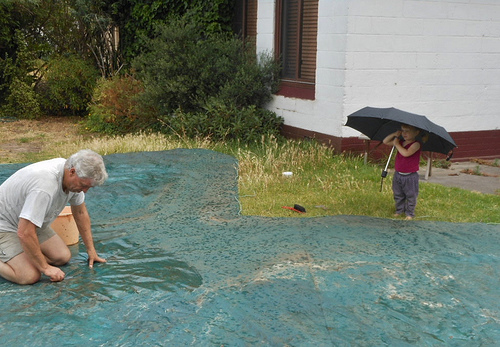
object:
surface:
[0, 236, 202, 345]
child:
[382, 123, 421, 221]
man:
[0, 150, 107, 284]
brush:
[84, 4, 287, 147]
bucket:
[48, 205, 81, 247]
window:
[227, 1, 257, 64]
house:
[220, 2, 497, 158]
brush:
[282, 204, 306, 214]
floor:
[449, 173, 500, 193]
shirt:
[393, 139, 421, 172]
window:
[268, 1, 319, 101]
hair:
[66, 150, 108, 185]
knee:
[14, 265, 41, 286]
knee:
[52, 250, 71, 265]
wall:
[255, 1, 497, 138]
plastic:
[2, 147, 497, 346]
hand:
[84, 253, 107, 268]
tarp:
[2, 135, 497, 345]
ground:
[2, 98, 498, 345]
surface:
[143, 214, 373, 334]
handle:
[380, 142, 395, 178]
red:
[392, 152, 402, 167]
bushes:
[4, 77, 41, 119]